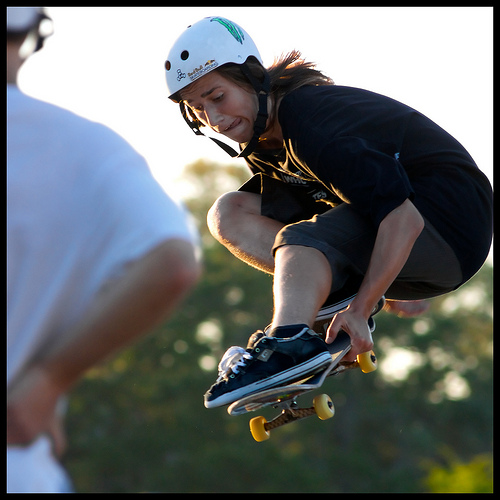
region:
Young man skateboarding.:
[155, 13, 491, 446]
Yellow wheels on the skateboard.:
[245, 350, 382, 448]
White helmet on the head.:
[158, 13, 275, 150]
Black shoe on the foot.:
[195, 321, 333, 413]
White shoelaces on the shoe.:
[216, 340, 253, 380]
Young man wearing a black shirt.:
[161, 15, 498, 295]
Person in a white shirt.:
[0, 8, 197, 497]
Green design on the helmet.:
[205, 16, 246, 45]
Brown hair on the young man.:
[174, 40, 328, 132]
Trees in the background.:
[58, 148, 492, 493]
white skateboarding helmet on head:
[157, 11, 252, 91]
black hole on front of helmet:
[180, 45, 194, 61]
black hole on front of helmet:
[158, 58, 174, 73]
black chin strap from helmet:
[248, 77, 269, 149]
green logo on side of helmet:
[210, 8, 241, 52]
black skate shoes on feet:
[194, 331, 326, 413]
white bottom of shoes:
[277, 357, 333, 383]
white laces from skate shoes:
[225, 346, 248, 371]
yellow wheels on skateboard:
[312, 393, 334, 415]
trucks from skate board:
[260, 403, 314, 434]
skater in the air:
[145, 11, 498, 442]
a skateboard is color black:
[223, 313, 380, 444]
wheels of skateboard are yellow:
[248, 349, 384, 443]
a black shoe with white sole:
[193, 320, 338, 417]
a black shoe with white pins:
[194, 322, 339, 413]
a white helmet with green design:
[146, 11, 271, 97]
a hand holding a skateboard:
[196, 205, 410, 432]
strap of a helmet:
[174, 78, 274, 170]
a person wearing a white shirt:
[8, 5, 200, 487]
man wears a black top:
[145, 18, 498, 446]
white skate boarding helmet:
[165, 20, 257, 107]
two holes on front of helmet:
[166, 48, 191, 73]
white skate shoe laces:
[215, 343, 245, 368]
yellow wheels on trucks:
[312, 394, 337, 419]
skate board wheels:
[245, 386, 339, 437]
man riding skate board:
[137, 12, 486, 434]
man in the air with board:
[137, 3, 472, 443]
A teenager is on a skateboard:
[165, 25, 485, 431]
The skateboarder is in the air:
[177, 121, 462, 432]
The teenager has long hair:
[209, 36, 336, 131]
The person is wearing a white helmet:
[145, 8, 272, 107]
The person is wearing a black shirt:
[269, 64, 494, 275]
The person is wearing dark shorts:
[242, 175, 469, 318]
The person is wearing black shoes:
[202, 334, 355, 400]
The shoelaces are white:
[212, 338, 250, 373]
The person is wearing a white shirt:
[0, 48, 185, 420]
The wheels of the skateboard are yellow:
[235, 348, 398, 447]